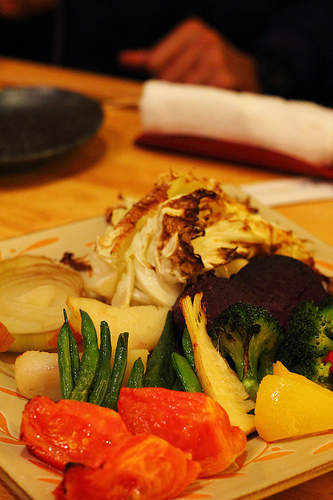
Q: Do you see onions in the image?
A: Yes, there are onions.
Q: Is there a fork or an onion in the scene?
A: Yes, there are onions.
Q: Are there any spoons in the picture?
A: No, there are no spoons.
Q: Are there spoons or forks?
A: No, there are no spoons or forks.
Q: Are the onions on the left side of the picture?
A: Yes, the onions are on the left of the image.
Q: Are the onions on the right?
A: No, the onions are on the left of the image.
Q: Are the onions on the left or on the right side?
A: The onions are on the left of the image.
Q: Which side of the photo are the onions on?
A: The onions are on the left of the image.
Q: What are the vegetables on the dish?
A: The vegetables are onions.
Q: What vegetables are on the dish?
A: The vegetables are onions.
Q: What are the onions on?
A: The onions are on the dish.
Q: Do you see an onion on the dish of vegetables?
A: Yes, there are onions on the dish.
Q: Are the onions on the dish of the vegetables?
A: Yes, the onions are on the dish.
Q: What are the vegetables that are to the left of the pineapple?
A: The vegetables are onions.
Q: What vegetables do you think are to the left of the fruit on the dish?
A: The vegetables are onions.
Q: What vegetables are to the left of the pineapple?
A: The vegetables are onions.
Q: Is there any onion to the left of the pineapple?
A: Yes, there are onions to the left of the pineapple.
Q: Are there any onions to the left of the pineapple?
A: Yes, there are onions to the left of the pineapple.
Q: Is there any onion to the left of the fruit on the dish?
A: Yes, there are onions to the left of the pineapple.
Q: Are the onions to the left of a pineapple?
A: Yes, the onions are to the left of a pineapple.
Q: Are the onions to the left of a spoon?
A: No, the onions are to the left of a pineapple.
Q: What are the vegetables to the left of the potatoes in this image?
A: The vegetables are onions.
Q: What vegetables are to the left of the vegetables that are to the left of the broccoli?
A: The vegetables are onions.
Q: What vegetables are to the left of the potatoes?
A: The vegetables are onions.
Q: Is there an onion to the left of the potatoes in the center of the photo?
A: Yes, there are onions to the left of the potatoes.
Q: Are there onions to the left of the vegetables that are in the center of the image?
A: Yes, there are onions to the left of the potatoes.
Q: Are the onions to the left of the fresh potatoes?
A: Yes, the onions are to the left of the potatoes.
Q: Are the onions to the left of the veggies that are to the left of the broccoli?
A: Yes, the onions are to the left of the potatoes.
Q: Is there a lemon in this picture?
A: Yes, there is a lemon.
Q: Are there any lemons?
A: Yes, there is a lemon.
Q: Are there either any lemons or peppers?
A: Yes, there is a lemon.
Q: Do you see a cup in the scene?
A: No, there are no cups.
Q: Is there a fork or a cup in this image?
A: No, there are no cups or forks.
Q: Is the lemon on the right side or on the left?
A: The lemon is on the right of the image.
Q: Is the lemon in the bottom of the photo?
A: Yes, the lemon is in the bottom of the image.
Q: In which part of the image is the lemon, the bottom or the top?
A: The lemon is in the bottom of the image.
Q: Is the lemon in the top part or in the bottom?
A: The lemon is in the bottom of the image.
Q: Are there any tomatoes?
A: Yes, there are tomatoes.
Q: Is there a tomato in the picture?
A: Yes, there are tomatoes.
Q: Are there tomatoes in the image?
A: Yes, there are tomatoes.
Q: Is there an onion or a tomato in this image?
A: Yes, there are tomatoes.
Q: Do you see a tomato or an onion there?
A: Yes, there are tomatoes.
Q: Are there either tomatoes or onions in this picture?
A: Yes, there are tomatoes.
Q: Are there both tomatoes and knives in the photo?
A: No, there are tomatoes but no knives.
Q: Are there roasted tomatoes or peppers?
A: Yes, there are roasted tomatoes.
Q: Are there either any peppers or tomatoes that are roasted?
A: Yes, the tomatoes are roasted.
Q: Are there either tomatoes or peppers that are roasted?
A: Yes, the tomatoes are roasted.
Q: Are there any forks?
A: No, there are no forks.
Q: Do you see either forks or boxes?
A: No, there are no forks or boxes.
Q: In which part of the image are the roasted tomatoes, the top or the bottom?
A: The tomatoes are in the bottom of the image.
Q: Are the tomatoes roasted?
A: Yes, the tomatoes are roasted.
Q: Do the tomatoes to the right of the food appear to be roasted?
A: Yes, the tomatoes are roasted.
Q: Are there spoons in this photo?
A: No, there are no spoons.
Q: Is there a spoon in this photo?
A: No, there are no spoons.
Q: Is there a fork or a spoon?
A: No, there are no spoons or forks.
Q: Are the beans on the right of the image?
A: No, the beans are on the left of the image.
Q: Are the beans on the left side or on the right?
A: The beans are on the left of the image.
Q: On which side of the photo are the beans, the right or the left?
A: The beans are on the left of the image.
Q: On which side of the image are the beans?
A: The beans are on the left of the image.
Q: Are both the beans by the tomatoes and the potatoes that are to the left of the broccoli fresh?
A: Yes, both the beans and the potatoes are fresh.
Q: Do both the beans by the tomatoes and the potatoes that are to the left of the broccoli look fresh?
A: Yes, both the beans and the potatoes are fresh.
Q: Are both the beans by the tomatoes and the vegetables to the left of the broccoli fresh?
A: Yes, both the beans and the potatoes are fresh.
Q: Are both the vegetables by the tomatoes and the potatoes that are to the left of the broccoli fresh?
A: Yes, both the beans and the potatoes are fresh.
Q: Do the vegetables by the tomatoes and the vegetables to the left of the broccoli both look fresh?
A: Yes, both the beans and the potatoes are fresh.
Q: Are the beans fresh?
A: Yes, the beans are fresh.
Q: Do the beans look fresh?
A: Yes, the beans are fresh.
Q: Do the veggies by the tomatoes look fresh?
A: Yes, the beans are fresh.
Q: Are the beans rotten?
A: No, the beans are fresh.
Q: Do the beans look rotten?
A: No, the beans are fresh.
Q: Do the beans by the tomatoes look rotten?
A: No, the beans are fresh.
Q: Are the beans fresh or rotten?
A: The beans are fresh.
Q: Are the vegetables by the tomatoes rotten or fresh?
A: The beans are fresh.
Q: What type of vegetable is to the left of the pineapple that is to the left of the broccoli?
A: The vegetables are beans.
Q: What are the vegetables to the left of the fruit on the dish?
A: The vegetables are beans.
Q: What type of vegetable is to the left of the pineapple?
A: The vegetables are beans.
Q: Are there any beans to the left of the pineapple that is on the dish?
A: Yes, there are beans to the left of the pineapple.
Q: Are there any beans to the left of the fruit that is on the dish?
A: Yes, there are beans to the left of the pineapple.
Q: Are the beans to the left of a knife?
A: No, the beans are to the left of the pineapple.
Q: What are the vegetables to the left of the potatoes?
A: The vegetables are beans.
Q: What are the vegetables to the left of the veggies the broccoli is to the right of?
A: The vegetables are beans.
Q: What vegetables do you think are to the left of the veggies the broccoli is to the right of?
A: The vegetables are beans.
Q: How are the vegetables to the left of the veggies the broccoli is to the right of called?
A: The vegetables are beans.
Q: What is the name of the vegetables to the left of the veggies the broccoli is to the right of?
A: The vegetables are beans.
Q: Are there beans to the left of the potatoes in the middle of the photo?
A: Yes, there are beans to the left of the potatoes.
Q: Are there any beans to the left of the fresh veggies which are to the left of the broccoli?
A: Yes, there are beans to the left of the potatoes.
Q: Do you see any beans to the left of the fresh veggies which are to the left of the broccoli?
A: Yes, there are beans to the left of the potatoes.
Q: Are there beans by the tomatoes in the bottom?
A: Yes, there are beans by the tomatoes.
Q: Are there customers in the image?
A: No, there are no customers.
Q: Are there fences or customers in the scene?
A: No, there are no customers or fences.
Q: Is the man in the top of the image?
A: Yes, the man is in the top of the image.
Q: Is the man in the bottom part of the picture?
A: No, the man is in the top of the image.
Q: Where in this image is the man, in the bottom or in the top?
A: The man is in the top of the image.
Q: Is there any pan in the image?
A: Yes, there is a pan.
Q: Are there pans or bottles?
A: Yes, there is a pan.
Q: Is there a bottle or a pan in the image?
A: Yes, there is a pan.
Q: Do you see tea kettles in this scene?
A: No, there are no tea kettles.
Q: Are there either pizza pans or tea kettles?
A: No, there are no tea kettles or pizza pans.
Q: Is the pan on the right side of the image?
A: No, the pan is on the left of the image.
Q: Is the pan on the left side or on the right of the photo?
A: The pan is on the left of the image.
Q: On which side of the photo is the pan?
A: The pan is on the left of the image.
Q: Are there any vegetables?
A: Yes, there are vegetables.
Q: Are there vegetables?
A: Yes, there are vegetables.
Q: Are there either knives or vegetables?
A: Yes, there are vegetables.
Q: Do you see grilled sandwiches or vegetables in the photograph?
A: Yes, there are grilled vegetables.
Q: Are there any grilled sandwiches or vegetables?
A: Yes, there are grilled vegetables.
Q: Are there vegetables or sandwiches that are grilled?
A: Yes, the vegetables are grilled.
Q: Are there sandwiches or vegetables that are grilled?
A: Yes, the vegetables are grilled.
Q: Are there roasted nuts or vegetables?
A: Yes, there are roasted vegetables.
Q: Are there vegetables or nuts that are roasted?
A: Yes, the vegetables are roasted.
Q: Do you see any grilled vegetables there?
A: Yes, there are grilled vegetables.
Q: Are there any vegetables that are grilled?
A: Yes, there are vegetables that are grilled.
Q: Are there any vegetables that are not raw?
A: Yes, there are grilled vegetables.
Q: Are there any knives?
A: No, there are no knives.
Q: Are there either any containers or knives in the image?
A: No, there are no knives or containers.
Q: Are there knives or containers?
A: No, there are no knives or containers.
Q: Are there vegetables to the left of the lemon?
A: Yes, there are vegetables to the left of the lemon.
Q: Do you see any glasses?
A: No, there are no glasses.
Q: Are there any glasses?
A: No, there are no glasses.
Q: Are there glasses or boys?
A: No, there are no glasses or boys.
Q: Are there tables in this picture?
A: Yes, there is a table.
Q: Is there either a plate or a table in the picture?
A: Yes, there is a table.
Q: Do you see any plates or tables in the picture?
A: Yes, there is a table.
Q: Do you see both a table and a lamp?
A: No, there is a table but no lamps.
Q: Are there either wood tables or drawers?
A: Yes, there is a wood table.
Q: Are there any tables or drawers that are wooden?
A: Yes, the table is wooden.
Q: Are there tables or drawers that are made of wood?
A: Yes, the table is made of wood.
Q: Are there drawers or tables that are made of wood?
A: Yes, the table is made of wood.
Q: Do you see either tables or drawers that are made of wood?
A: Yes, the table is made of wood.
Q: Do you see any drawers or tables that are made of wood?
A: Yes, the table is made of wood.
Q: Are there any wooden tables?
A: Yes, there is a wood table.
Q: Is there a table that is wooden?
A: Yes, there is a table that is wooden.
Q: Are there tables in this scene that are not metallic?
A: Yes, there is a wooden table.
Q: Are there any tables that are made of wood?
A: Yes, there is a table that is made of wood.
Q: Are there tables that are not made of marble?
A: Yes, there is a table that is made of wood.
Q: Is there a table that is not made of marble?
A: Yes, there is a table that is made of wood.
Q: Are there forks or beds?
A: No, there are no forks or beds.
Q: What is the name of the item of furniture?
A: The piece of furniture is a table.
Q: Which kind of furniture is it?
A: The piece of furniture is a table.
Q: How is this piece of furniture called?
A: This is a table.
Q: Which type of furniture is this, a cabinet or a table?
A: This is a table.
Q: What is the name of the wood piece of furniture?
A: The piece of furniture is a table.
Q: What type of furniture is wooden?
A: The furniture is a table.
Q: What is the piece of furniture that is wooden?
A: The piece of furniture is a table.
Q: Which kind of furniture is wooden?
A: The furniture is a table.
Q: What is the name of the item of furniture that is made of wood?
A: The piece of furniture is a table.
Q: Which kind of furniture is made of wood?
A: The furniture is a table.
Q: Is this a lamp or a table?
A: This is a table.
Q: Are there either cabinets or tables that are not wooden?
A: No, there is a table but it is wooden.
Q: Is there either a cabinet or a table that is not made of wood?
A: No, there is a table but it is made of wood.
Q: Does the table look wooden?
A: Yes, the table is wooden.